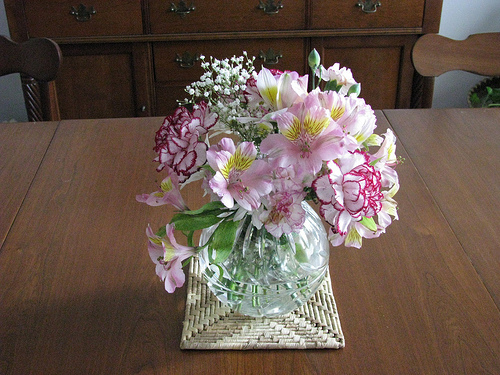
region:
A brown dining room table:
[1, 107, 498, 374]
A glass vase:
[197, 201, 331, 319]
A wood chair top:
[411, 30, 499, 110]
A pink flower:
[142, 221, 199, 294]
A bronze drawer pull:
[354, 0, 383, 13]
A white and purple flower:
[151, 101, 220, 183]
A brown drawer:
[1, 0, 145, 39]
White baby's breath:
[174, 47, 278, 143]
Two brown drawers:
[144, 0, 310, 84]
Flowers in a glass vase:
[133, 46, 406, 318]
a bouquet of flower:
[131, 35, 408, 305]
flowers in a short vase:
[144, 50, 384, 330]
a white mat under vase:
[154, 239, 352, 371]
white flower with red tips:
[296, 138, 393, 232]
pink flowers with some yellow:
[208, 111, 347, 225]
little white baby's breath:
[182, 47, 269, 139]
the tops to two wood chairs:
[9, 28, 498, 102]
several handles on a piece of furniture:
[154, 1, 319, 88]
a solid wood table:
[13, 105, 498, 354]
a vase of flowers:
[102, 50, 431, 367]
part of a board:
[79, 232, 118, 267]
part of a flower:
[271, 198, 315, 294]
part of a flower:
[291, 128, 318, 183]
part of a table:
[397, 270, 435, 326]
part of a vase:
[256, 259, 281, 296]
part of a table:
[375, 268, 419, 339]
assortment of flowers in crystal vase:
[143, 52, 404, 344]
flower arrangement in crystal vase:
[148, 49, 385, 314]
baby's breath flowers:
[186, 46, 261, 101]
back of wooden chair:
[408, 31, 498, 106]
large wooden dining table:
[1, 109, 498, 372]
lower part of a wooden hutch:
[3, 0, 443, 120]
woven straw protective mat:
[188, 245, 343, 348]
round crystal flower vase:
[196, 198, 331, 318]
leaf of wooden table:
[386, 106, 498, 311]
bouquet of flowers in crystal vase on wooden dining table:
[3, 3, 498, 373]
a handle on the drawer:
[67, 3, 105, 27]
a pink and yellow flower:
[200, 135, 276, 215]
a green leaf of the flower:
[202, 211, 249, 271]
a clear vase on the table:
[193, 195, 331, 324]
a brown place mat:
[175, 245, 350, 360]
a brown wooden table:
[0, 105, 499, 374]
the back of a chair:
[0, 31, 71, 83]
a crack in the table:
[0, 115, 65, 252]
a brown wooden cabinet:
[26, 38, 156, 125]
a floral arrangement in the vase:
[133, 35, 405, 308]